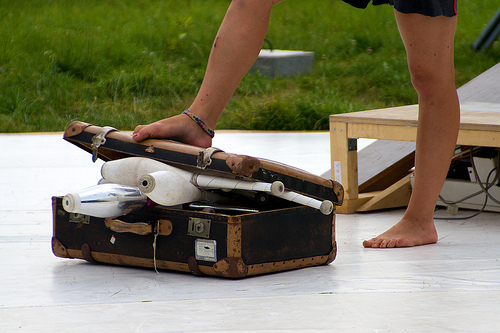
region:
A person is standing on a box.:
[27, 5, 446, 300]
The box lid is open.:
[32, 97, 359, 284]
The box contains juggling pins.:
[35, 109, 335, 277]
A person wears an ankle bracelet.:
[121, 7, 305, 142]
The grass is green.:
[7, 8, 174, 110]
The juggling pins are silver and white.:
[50, 138, 337, 231]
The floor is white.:
[1, 136, 377, 331]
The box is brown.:
[52, 108, 355, 286]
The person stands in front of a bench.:
[319, 70, 493, 245]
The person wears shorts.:
[230, 0, 482, 128]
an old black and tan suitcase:
[51, 120, 343, 281]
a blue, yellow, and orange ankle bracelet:
[178, 105, 214, 135]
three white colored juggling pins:
[60, 155, 215, 220]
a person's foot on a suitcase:
[47, 1, 342, 276]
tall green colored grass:
[0, 0, 496, 131]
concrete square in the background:
[250, 46, 315, 72]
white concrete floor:
[0, 131, 495, 321]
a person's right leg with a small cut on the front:
[131, 0, 274, 144]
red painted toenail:
[132, 128, 140, 140]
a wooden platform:
[326, 104, 498, 214]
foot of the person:
[121, 93, 241, 157]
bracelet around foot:
[177, 94, 228, 141]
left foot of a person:
[356, 188, 461, 270]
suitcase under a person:
[21, 90, 358, 300]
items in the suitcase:
[56, 161, 268, 250]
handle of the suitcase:
[96, 208, 161, 257]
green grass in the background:
[28, 27, 132, 92]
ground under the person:
[328, 259, 419, 320]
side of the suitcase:
[227, 202, 339, 274]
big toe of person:
[124, 125, 156, 144]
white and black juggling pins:
[64, 153, 344, 225]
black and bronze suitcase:
[51, 115, 343, 283]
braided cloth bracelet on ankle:
[163, 99, 230, 151]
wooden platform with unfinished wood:
[308, 102, 498, 219]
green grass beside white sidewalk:
[1, 0, 498, 146]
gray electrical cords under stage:
[432, 138, 497, 227]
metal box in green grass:
[228, 40, 328, 84]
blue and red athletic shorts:
[333, 0, 478, 22]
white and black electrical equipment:
[408, 138, 499, 215]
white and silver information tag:
[192, 238, 222, 263]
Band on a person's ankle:
[181, 108, 223, 138]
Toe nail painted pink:
[131, 133, 141, 140]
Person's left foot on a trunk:
[132, 108, 229, 149]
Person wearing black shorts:
[325, 0, 470, 25]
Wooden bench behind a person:
[321, 94, 499, 222]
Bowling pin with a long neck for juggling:
[95, 155, 287, 198]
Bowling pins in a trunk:
[55, 150, 336, 221]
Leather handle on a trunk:
[101, 214, 173, 239]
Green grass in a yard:
[2, 0, 493, 127]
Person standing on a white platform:
[2, 134, 497, 331]